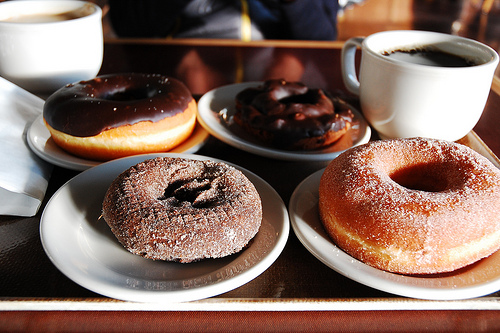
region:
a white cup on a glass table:
[337, 30, 497, 142]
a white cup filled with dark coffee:
[340, 25, 497, 145]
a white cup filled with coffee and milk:
[0, 0, 105, 90]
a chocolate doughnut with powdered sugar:
[100, 155, 260, 260]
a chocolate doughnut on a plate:
[42, 65, 197, 155]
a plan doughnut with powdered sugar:
[320, 136, 496, 267]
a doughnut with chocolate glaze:
[230, 80, 350, 147]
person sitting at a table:
[105, 0, 337, 36]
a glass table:
[1, 36, 497, 307]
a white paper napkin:
[1, 74, 45, 217]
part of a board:
[316, 304, 331, 316]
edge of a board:
[290, 310, 297, 320]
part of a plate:
[231, 284, 237, 294]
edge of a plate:
[148, 268, 157, 280]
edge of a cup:
[377, 106, 386, 116]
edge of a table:
[292, 310, 302, 324]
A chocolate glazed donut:
[37, 74, 204, 154]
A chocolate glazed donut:
[221, 78, 354, 148]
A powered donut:
[107, 155, 264, 258]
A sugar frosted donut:
[320, 134, 499, 260]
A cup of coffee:
[340, 34, 498, 134]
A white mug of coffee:
[336, 31, 498, 147]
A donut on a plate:
[58, 150, 292, 300]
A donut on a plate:
[300, 147, 499, 292]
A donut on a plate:
[198, 79, 376, 158]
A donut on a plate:
[27, 68, 207, 176]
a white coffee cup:
[344, 24, 496, 141]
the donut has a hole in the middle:
[387, 154, 477, 200]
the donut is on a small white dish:
[38, 158, 290, 302]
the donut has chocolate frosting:
[41, 72, 193, 150]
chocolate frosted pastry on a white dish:
[198, 76, 377, 154]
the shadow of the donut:
[71, 151, 152, 247]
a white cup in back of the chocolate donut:
[0, 1, 106, 84]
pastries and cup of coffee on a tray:
[1, 27, 498, 315]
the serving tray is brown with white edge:
[251, 235, 351, 309]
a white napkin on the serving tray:
[1, 77, 49, 223]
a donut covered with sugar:
[302, 127, 468, 265]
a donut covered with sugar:
[88, 158, 280, 290]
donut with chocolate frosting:
[34, 44, 177, 156]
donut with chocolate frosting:
[239, 63, 353, 152]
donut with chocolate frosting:
[53, 68, 207, 141]